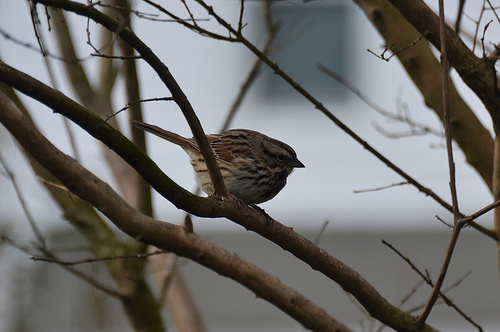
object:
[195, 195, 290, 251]
branch part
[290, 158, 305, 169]
beak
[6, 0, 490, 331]
sky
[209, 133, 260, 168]
wing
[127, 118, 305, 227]
bird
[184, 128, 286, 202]
body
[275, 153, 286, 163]
eye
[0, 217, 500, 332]
floor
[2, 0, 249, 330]
tree branch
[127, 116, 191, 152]
tail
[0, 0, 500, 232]
house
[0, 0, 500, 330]
branch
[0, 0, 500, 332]
tree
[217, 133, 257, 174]
stripe